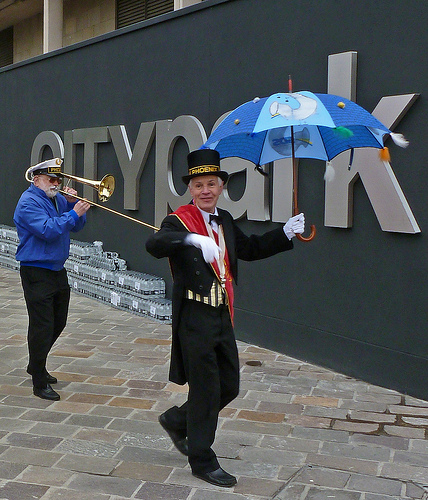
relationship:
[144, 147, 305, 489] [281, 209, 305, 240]
man wears glove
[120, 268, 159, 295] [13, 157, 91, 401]
bottles behind man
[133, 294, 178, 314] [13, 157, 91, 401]
bottles behind man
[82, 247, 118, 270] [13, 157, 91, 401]
bottles behind man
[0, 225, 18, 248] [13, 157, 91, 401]
bottles behind man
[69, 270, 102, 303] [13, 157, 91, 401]
bottles behind man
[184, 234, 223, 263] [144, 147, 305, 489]
gloves on man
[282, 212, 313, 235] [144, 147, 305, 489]
gloves on man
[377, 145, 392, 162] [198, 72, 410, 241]
feather on umbrella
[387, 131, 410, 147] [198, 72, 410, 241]
feather on umbrella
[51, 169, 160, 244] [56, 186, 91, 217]
trombone in hands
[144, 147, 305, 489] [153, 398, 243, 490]
man wears shoes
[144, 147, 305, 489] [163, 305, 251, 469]
man wears pants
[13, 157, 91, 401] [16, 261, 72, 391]
man wears black pants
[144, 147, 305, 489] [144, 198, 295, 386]
man wears black coat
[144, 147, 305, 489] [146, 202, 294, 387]
man wears black coat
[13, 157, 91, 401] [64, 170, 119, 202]
man plays trombone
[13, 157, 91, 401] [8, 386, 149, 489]
man on street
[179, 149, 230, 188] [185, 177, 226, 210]
top hat on head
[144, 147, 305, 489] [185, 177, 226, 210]
man has head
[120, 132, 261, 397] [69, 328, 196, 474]
man on cement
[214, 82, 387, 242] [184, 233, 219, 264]
umbrella in hand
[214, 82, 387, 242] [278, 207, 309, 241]
umbrella in hand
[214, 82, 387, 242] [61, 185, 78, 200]
umbrella in hand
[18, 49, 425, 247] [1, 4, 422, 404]
letters on a sign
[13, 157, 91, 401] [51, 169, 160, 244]
man playing trombone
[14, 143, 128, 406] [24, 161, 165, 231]
man playing trombone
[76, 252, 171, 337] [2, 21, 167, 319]
bottles stacked against wall